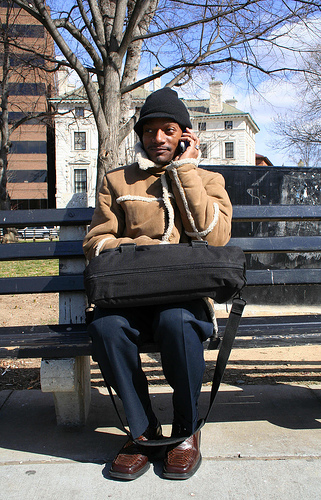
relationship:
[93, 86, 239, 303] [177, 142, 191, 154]
man holding cellphone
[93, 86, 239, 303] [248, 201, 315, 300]
man sitting on bench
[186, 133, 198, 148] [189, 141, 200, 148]
finger has a ring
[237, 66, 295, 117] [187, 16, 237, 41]
clouds in sky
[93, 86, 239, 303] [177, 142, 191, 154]
man talking on cellphone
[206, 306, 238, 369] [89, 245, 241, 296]
strap on bag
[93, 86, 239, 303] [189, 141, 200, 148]
man has a ring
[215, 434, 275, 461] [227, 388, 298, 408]
ground has shadows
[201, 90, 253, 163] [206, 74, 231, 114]
building has a chimney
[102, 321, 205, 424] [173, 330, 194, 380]
pants have crease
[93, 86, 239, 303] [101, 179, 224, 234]
man a jacket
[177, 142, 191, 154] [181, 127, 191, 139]
cellphone next to ear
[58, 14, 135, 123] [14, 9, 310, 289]
tree in winter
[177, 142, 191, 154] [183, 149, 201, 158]
cellphone in a hand